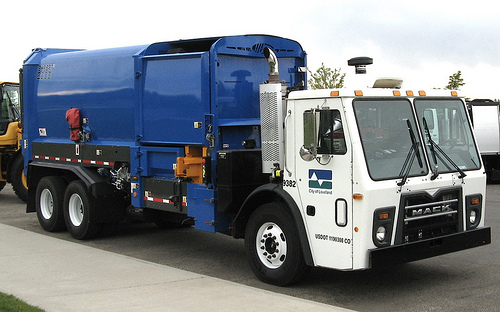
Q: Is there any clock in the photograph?
A: No, there are no clocks.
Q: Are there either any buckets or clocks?
A: No, there are no clocks or buckets.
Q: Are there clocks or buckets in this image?
A: No, there are no clocks or buckets.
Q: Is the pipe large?
A: Yes, the pipe is large.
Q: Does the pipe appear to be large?
A: Yes, the pipe is large.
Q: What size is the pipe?
A: The pipe is large.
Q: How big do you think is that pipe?
A: The pipe is large.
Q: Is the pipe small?
A: No, the pipe is large.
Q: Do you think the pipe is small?
A: No, the pipe is large.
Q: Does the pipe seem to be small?
A: No, the pipe is large.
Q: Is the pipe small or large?
A: The pipe is large.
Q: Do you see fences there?
A: No, there are no fences.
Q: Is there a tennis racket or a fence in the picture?
A: No, there are no fences or rackets.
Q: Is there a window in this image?
A: Yes, there is a window.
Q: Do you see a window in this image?
A: Yes, there is a window.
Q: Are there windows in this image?
A: Yes, there is a window.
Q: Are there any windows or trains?
A: Yes, there is a window.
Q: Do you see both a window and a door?
A: Yes, there are both a window and a door.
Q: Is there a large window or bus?
A: Yes, there is a large window.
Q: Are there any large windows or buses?
A: Yes, there is a large window.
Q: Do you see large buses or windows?
A: Yes, there is a large window.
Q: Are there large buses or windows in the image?
A: Yes, there is a large window.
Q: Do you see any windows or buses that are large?
A: Yes, the window is large.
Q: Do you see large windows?
A: Yes, there is a large window.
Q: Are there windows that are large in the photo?
A: Yes, there is a large window.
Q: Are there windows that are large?
A: Yes, there is a window that is large.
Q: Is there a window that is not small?
A: Yes, there is a large window.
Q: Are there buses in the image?
A: No, there are no buses.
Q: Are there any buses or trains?
A: No, there are no buses or trains.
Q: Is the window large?
A: Yes, the window is large.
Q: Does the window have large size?
A: Yes, the window is large.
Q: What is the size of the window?
A: The window is large.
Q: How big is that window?
A: The window is large.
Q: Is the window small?
A: No, the window is large.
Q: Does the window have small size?
A: No, the window is large.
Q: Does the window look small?
A: No, the window is large.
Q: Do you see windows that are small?
A: No, there is a window but it is large.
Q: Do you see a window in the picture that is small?
A: No, there is a window but it is large.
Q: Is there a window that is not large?
A: No, there is a window but it is large.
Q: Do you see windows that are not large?
A: No, there is a window but it is large.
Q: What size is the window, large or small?
A: The window is large.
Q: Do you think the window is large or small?
A: The window is large.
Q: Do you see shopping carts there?
A: No, there are no shopping carts.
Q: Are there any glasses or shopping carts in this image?
A: No, there are no shopping carts or glasses.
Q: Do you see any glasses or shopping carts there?
A: No, there are no shopping carts or glasses.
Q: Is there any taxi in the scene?
A: Yes, there is a taxi.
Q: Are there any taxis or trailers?
A: Yes, there is a taxi.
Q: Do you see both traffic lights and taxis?
A: No, there is a taxi but no traffic lights.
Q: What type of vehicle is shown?
A: The vehicle is a taxi.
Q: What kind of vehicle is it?
A: The vehicle is a taxi.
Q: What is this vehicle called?
A: This is a taxi.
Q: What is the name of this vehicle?
A: This is a taxi.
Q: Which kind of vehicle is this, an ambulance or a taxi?
A: This is a taxi.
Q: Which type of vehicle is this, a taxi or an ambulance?
A: This is a taxi.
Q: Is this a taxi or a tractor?
A: This is a taxi.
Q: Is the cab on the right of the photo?
A: Yes, the cab is on the right of the image.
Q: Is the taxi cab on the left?
A: No, the taxi cab is on the right of the image.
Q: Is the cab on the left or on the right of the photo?
A: The cab is on the right of the image.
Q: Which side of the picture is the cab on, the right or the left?
A: The cab is on the right of the image.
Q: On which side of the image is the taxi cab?
A: The taxi cab is on the right of the image.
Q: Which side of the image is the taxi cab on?
A: The taxi cab is on the right of the image.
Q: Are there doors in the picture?
A: Yes, there is a door.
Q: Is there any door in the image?
A: Yes, there is a door.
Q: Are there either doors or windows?
A: Yes, there is a door.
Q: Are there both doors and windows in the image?
A: Yes, there are both a door and a window.